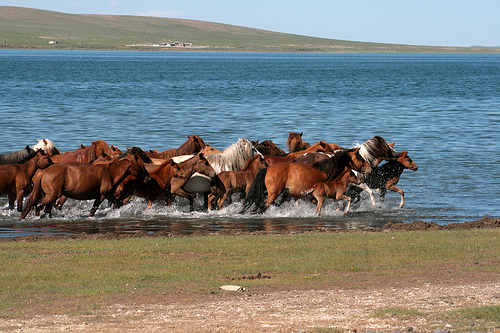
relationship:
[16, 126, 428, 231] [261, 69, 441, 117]
horses running in water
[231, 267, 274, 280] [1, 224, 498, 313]
dung on grass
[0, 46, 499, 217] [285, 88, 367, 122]
across water with ripples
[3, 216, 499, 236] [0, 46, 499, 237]
mud piles along water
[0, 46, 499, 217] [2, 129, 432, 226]
across water splashing from horses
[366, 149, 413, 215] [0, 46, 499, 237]
horse running through water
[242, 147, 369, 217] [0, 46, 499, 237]
horse running through water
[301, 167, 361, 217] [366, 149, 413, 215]
foal running through horse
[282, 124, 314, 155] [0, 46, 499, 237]
horse running through water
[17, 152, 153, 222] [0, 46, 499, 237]
horse running through water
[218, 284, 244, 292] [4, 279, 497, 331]
flat rock partially buried in sand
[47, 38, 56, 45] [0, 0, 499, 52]
building on green hill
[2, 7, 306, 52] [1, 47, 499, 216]
hill on or side of water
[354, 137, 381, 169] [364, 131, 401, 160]
mane on head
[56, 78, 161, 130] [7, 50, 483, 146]
ripples are in water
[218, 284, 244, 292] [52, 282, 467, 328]
flat rock on ground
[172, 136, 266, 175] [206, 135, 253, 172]
horse has white mane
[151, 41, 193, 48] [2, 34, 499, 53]
building in clearing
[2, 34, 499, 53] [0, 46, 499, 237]
clearing behind water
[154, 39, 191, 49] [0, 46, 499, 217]
building on side of across water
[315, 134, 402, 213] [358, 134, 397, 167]
horse has mane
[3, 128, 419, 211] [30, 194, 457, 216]
herd kicking up water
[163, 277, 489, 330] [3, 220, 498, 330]
pathway on land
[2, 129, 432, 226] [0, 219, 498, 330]
horses on beach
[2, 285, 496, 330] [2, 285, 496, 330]
dirt of dirt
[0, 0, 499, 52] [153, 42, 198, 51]
hill behind buildings